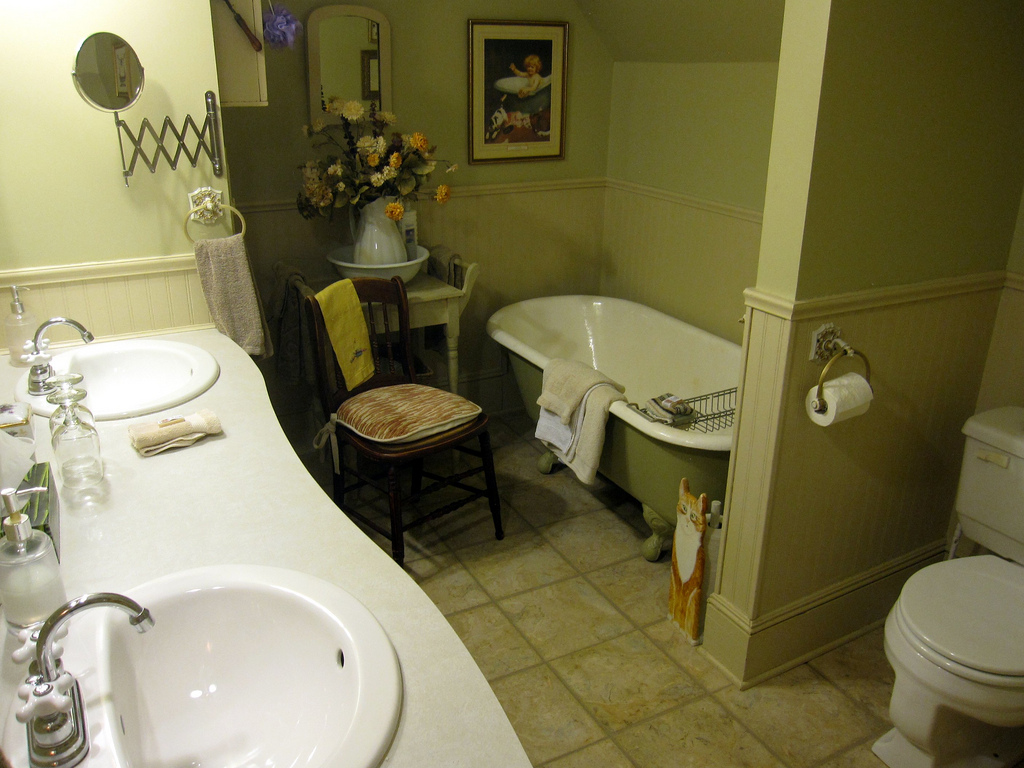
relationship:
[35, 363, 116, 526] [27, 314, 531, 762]
glasses on sink counter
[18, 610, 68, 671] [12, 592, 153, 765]
right knob on faucet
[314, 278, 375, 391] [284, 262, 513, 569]
towel on chair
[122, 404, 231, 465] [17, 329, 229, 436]
towel on sink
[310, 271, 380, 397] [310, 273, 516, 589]
towel on chair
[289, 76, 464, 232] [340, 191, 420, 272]
flowers in vase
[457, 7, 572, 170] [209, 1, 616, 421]
art on wall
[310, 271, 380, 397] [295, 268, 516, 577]
towel on chair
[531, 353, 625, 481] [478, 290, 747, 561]
towel on bath tub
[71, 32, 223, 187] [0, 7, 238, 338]
mirror extending from wall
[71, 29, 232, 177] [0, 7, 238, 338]
mirror on wall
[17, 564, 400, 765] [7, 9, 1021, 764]
sink in bathroom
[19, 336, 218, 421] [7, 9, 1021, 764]
sink in bathroom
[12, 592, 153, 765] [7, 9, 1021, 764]
faucet in bathroom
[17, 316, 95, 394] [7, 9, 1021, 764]
faucet in bathroom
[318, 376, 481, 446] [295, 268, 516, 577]
pad on chair